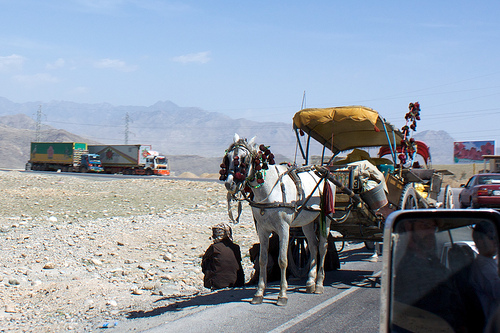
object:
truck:
[28, 141, 103, 174]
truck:
[86, 144, 171, 175]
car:
[458, 173, 499, 209]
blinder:
[236, 154, 249, 180]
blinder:
[220, 154, 230, 180]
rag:
[211, 222, 231, 241]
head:
[210, 223, 231, 243]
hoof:
[277, 296, 290, 305]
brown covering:
[293, 106, 411, 153]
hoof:
[252, 296, 265, 304]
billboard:
[451, 140, 495, 163]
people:
[200, 223, 246, 290]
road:
[137, 242, 382, 332]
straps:
[226, 192, 245, 222]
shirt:
[202, 241, 243, 286]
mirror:
[383, 210, 500, 332]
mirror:
[458, 183, 465, 186]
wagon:
[220, 105, 454, 305]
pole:
[304, 135, 310, 163]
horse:
[221, 132, 338, 306]